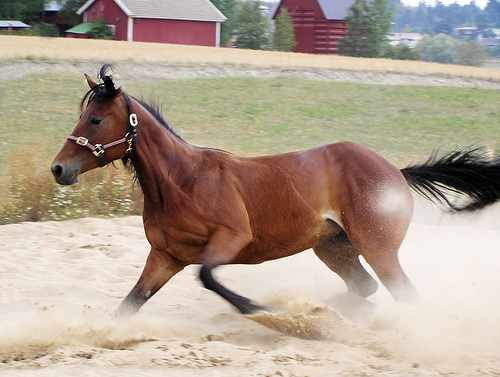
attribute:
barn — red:
[268, 0, 379, 56]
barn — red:
[76, 0, 226, 44]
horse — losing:
[59, 51, 484, 343]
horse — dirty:
[44, 61, 496, 333]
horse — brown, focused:
[51, 65, 499, 314]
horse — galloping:
[34, 75, 472, 345]